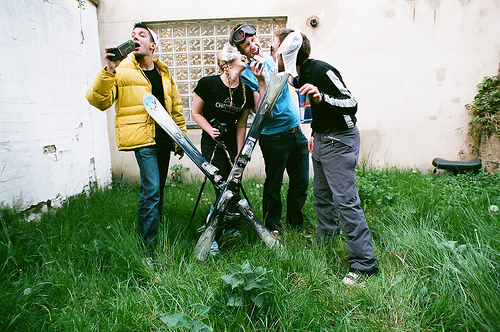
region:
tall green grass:
[2, 163, 491, 329]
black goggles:
[222, 25, 258, 48]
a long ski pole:
[137, 92, 296, 255]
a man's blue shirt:
[243, 63, 303, 134]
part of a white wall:
[0, 0, 120, 226]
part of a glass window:
[142, 22, 289, 117]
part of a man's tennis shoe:
[337, 271, 362, 286]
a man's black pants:
[255, 130, 310, 224]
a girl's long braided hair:
[220, 57, 237, 105]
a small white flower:
[20, 285, 36, 296]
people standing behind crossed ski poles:
[87, 26, 383, 283]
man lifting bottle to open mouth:
[95, 17, 180, 97]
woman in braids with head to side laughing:
[195, 40, 255, 110]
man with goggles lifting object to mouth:
[232, 25, 262, 80]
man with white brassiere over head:
[265, 25, 310, 80]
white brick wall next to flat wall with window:
[1, 1, 492, 216]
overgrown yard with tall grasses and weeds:
[2, 170, 497, 325]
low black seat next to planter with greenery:
[430, 72, 495, 172]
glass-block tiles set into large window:
[125, 11, 285, 131]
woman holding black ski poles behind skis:
[176, 110, 254, 237]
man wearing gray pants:
[307, 122, 383, 282]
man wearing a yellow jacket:
[86, 58, 193, 140]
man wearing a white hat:
[129, 23, 167, 61]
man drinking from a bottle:
[96, 29, 148, 62]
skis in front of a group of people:
[128, 69, 326, 276]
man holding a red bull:
[290, 73, 315, 126]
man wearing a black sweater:
[292, 52, 364, 145]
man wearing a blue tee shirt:
[245, 58, 302, 131]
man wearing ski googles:
[223, 15, 264, 50]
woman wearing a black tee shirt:
[188, 70, 253, 143]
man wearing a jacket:
[101, 27, 181, 248]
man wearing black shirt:
[96, 18, 191, 254]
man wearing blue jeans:
[75, 16, 175, 246]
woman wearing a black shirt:
[175, 36, 245, 146]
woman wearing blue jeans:
[195, 35, 245, 160]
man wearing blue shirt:
[251, 21, 312, 228]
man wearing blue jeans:
[250, 15, 315, 220]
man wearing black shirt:
[280, 27, 390, 277]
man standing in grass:
[295, 53, 395, 298]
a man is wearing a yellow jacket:
[97, 63, 324, 185]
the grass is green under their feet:
[100, 238, 248, 291]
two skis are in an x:
[124, 92, 412, 327]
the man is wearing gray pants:
[308, 133, 418, 295]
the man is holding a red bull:
[287, 70, 343, 146]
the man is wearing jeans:
[132, 138, 184, 186]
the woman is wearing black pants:
[196, 128, 306, 240]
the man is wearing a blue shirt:
[240, 62, 357, 172]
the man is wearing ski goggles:
[207, 4, 300, 49]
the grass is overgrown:
[72, 230, 212, 288]